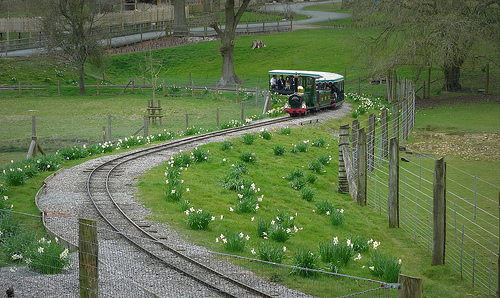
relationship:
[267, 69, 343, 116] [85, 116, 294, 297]
train on train tracks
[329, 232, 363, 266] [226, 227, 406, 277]
flower on ground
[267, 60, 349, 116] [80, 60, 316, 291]
train on train tracks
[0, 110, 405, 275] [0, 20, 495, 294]
flowers are in grass